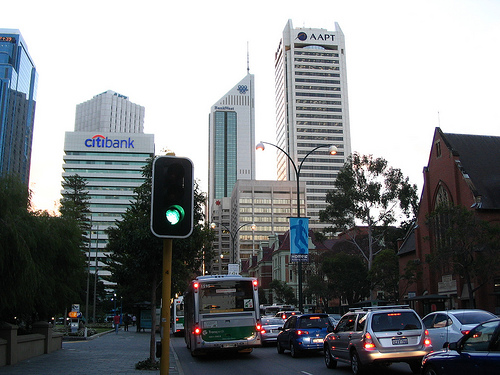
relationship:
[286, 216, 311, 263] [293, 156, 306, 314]
banner on pole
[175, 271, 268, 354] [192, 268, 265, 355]
bus has back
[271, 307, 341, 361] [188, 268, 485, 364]
car in traffic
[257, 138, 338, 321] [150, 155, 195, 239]
pole supporting light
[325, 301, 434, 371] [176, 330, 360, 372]
car parked on pavement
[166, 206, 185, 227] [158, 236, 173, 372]
greenlight on yellow pole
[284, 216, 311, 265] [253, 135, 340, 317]
banner on pole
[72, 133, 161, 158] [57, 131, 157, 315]
logo on building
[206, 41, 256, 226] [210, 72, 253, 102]
building with top